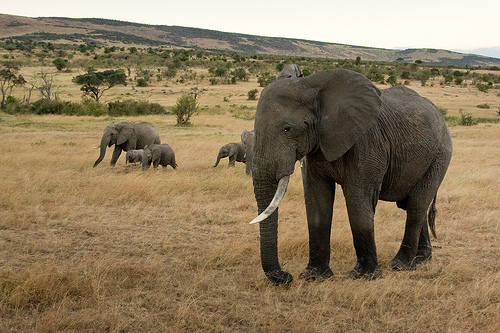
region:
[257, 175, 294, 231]
An elephant's left tusk.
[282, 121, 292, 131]
An elephant's left eye.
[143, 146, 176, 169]
A juvenile elephant.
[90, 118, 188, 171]
An adult elephant walking beside two younger ones.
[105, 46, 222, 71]
Green trees dotting the savanna.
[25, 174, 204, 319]
A patch of brown grass.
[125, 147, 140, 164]
A baby elephant walking between a juvenile and adult.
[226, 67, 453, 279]
An adult elephant standing alone.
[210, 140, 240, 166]
A young elephant lagging behind three others.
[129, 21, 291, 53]
A hillside sparsely dotted by trees.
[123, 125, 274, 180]
there are four small elephants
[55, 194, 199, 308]
the grasses are dry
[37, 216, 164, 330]
the grasses are brown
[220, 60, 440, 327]
the elephant has tusk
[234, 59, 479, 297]
the elephant is wrinkled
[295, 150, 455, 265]
the elephant has four legs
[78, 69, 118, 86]
the leaves are green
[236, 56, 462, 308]
the elephant is gray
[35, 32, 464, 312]
there are six elephants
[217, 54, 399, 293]
the elephant has two ears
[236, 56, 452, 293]
Gray elephant in field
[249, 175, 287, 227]
white tusk of elephant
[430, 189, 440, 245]
tail of gray elephant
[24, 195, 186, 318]
brown grass in field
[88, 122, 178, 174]
three elephants grazing together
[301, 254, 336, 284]
large gray foot of elephant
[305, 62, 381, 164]
Large gray right ear of elephant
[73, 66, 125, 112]
Tall tree in background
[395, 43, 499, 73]
Part of hillside in distance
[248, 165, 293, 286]
Gray elephant trunk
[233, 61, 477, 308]
A big elephant is in the foreground.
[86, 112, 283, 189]
Several elephants are in the background.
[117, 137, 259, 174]
Some of the elephants are babies.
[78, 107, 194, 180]
A mother elephant walks alongside the baby elephant.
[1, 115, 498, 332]
The elephants walk through grass.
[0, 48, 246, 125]
Shrubs and vegetation grow from the ground.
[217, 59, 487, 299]
The elephant is facing left.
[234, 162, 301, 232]
The elephant's tusk is visible.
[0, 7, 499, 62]
Hills are in the background.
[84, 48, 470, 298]
The elephants are gray.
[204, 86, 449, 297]
gray elephant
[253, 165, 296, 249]
large white tusk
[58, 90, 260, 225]
elephants in the background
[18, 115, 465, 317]
elephants in standing in field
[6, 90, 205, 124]
greenery in background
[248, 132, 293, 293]
long trunk on elephant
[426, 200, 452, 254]
hair on the tip of the elephant's tail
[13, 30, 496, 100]
hillside in the background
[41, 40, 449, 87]
trees and bushes in the background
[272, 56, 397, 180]
large ears on elephant